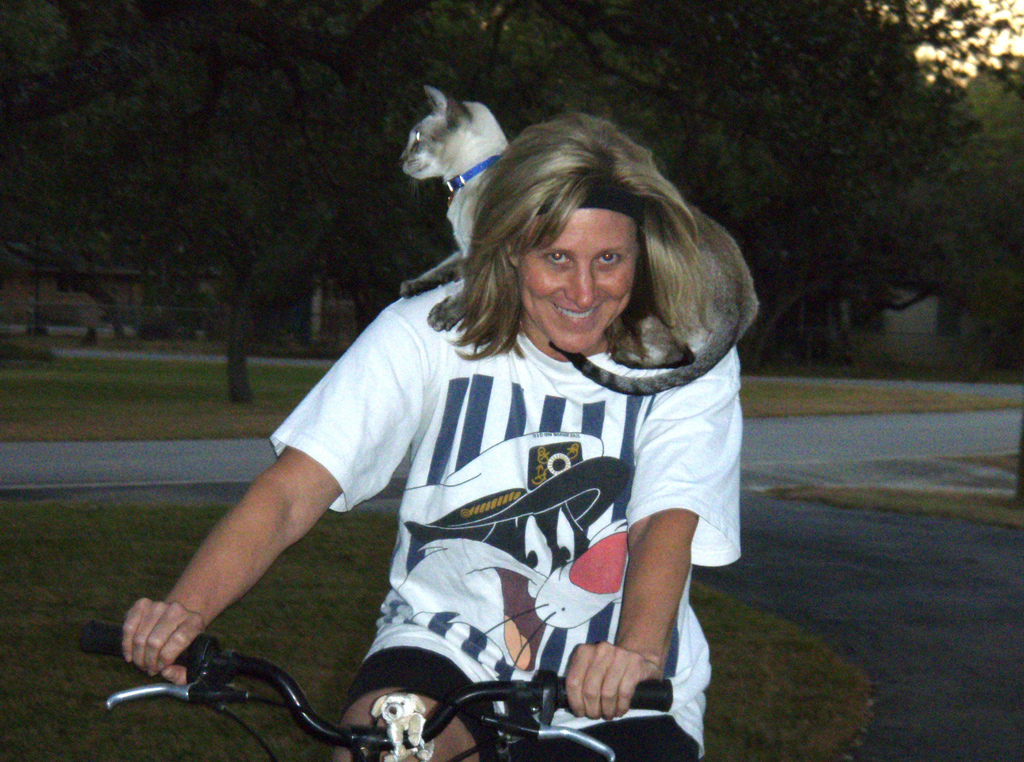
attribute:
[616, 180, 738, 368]
hair — blonde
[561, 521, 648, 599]
nose — red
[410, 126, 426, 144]
eye — open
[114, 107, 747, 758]
woman — blonde, smiling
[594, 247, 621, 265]
eye — red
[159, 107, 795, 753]
lady — shoulders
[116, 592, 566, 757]
bike — Handle bars 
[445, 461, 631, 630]
cartoon cat — white, Black 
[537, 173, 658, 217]
headband — black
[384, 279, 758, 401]
shoulder — lady 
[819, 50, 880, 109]
leaves — green